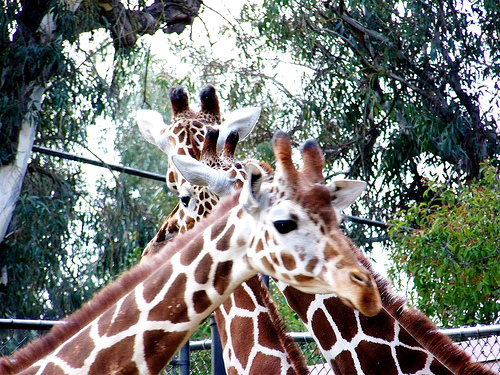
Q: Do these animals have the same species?
A: Yes, all the animals are giraffes.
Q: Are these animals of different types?
A: No, all the animals are giraffes.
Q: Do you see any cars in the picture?
A: No, there are no cars.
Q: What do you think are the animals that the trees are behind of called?
A: The animals are giraffes.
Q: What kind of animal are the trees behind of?
A: The trees are behind the giraffes.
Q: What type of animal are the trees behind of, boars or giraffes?
A: The trees are behind giraffes.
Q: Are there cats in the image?
A: No, there are no cats.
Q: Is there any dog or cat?
A: No, there are no cats or dogs.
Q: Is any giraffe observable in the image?
A: Yes, there are giraffes.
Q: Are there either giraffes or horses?
A: Yes, there are giraffes.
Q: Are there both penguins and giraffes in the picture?
A: No, there are giraffes but no penguins.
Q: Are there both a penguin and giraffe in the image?
A: No, there are giraffes but no penguins.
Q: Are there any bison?
A: No, there are no bison.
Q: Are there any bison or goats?
A: No, there are no bison or goats.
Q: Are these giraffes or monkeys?
A: These are giraffes.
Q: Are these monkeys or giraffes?
A: These are giraffes.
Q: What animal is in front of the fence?
A: The giraffes are in front of the fence.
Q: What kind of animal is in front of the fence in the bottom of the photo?
A: The animals are giraffes.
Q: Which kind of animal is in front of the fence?
A: The animals are giraffes.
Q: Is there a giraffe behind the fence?
A: No, the giraffes are in front of the fence.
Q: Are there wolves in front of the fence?
A: No, there are giraffes in front of the fence.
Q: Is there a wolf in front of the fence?
A: No, there are giraffes in front of the fence.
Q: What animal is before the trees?
A: The giraffes are in front of the trees.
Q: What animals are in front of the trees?
A: The animals are giraffes.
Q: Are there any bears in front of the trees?
A: No, there are giraffes in front of the trees.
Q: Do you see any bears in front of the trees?
A: No, there are giraffes in front of the trees.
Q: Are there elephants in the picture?
A: No, there are no elephants.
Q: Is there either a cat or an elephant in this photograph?
A: No, there are no elephants or cats.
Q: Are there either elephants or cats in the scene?
A: No, there are no elephants or cats.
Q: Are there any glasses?
A: No, there are no glasses.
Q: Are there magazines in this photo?
A: No, there are no magazines.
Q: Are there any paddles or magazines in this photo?
A: No, there are no magazines or paddles.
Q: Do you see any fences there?
A: Yes, there is a fence.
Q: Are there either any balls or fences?
A: Yes, there is a fence.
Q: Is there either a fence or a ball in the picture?
A: Yes, there is a fence.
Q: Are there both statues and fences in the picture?
A: No, there is a fence but no statues.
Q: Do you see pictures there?
A: No, there are no pictures.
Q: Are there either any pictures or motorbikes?
A: No, there are no pictures or motorbikes.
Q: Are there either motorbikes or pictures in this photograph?
A: No, there are no pictures or motorbikes.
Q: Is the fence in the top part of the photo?
A: No, the fence is in the bottom of the image.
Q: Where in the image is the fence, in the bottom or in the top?
A: The fence is in the bottom of the image.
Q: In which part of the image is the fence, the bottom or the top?
A: The fence is in the bottom of the image.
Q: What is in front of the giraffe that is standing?
A: The fence is in front of the giraffe.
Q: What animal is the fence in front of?
A: The fence is in front of the giraffe.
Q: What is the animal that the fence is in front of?
A: The animal is a giraffe.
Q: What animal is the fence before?
A: The fence is in front of the giraffe.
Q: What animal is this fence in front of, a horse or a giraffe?
A: The fence is in front of a giraffe.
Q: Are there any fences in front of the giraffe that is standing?
A: Yes, there is a fence in front of the giraffe.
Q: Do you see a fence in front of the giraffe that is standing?
A: Yes, there is a fence in front of the giraffe.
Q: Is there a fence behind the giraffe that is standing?
A: No, the fence is in front of the giraffe.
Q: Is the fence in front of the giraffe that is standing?
A: Yes, the fence is in front of the giraffe.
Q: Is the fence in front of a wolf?
A: No, the fence is in front of the giraffe.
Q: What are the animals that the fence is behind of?
A: The animals are giraffes.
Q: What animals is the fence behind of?
A: The fence is behind the giraffes.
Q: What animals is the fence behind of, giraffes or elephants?
A: The fence is behind giraffes.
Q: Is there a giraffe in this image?
A: Yes, there is a giraffe.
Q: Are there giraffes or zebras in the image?
A: Yes, there is a giraffe.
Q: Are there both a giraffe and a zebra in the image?
A: No, there is a giraffe but no zebras.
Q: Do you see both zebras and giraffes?
A: No, there is a giraffe but no zebras.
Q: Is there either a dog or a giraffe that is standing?
A: Yes, the giraffe is standing.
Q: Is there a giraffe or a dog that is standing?
A: Yes, the giraffe is standing.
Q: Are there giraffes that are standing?
A: Yes, there is a giraffe that is standing.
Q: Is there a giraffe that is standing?
A: Yes, there is a giraffe that is standing.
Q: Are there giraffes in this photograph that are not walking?
A: Yes, there is a giraffe that is standing.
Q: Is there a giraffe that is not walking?
A: Yes, there is a giraffe that is standing.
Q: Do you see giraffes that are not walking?
A: Yes, there is a giraffe that is standing .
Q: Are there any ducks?
A: No, there are no ducks.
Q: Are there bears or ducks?
A: No, there are no ducks or bears.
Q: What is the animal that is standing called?
A: The animal is a giraffe.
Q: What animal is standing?
A: The animal is a giraffe.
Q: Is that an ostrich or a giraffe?
A: That is a giraffe.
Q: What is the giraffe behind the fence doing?
A: The giraffe is standing.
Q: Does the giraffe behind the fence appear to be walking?
A: No, the giraffe is standing.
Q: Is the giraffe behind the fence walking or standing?
A: The giraffe is standing.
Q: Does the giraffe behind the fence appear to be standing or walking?
A: The giraffe is standing.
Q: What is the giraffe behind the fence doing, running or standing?
A: The giraffe is standing.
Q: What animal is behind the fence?
A: The animal is a giraffe.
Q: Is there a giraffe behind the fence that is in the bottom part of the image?
A: Yes, there is a giraffe behind the fence.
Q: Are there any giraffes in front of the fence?
A: No, the giraffe is behind the fence.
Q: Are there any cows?
A: No, there are no cows.